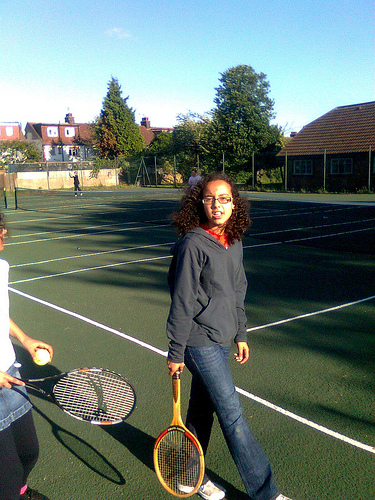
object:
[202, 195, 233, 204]
glasses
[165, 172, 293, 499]
young lady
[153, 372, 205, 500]
tennis racket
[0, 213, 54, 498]
person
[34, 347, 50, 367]
tennis ball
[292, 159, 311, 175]
window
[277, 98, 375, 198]
building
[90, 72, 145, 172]
tree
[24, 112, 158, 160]
another building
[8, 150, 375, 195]
fence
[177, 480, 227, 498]
shoe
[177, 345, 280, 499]
jeans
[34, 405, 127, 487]
shadow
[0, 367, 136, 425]
tennis racket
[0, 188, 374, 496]
court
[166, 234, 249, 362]
sweatshirt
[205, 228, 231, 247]
undershirt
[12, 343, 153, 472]
shadow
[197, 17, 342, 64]
part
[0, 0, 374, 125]
sky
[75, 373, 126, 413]
part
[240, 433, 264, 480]
part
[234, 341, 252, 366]
left hand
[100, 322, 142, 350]
part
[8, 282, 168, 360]
white line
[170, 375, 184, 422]
handle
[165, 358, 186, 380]
right hand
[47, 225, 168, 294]
patch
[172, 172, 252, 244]
hair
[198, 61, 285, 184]
large tree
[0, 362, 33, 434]
skirt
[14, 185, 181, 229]
net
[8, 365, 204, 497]
rackets